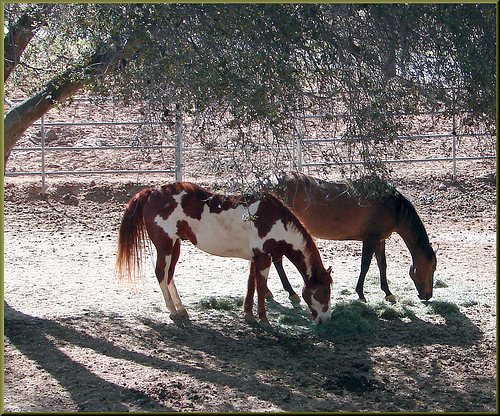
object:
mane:
[282, 195, 325, 275]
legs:
[254, 254, 274, 328]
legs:
[151, 256, 178, 320]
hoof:
[256, 311, 276, 331]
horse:
[113, 177, 337, 327]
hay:
[310, 323, 339, 339]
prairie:
[0, 176, 499, 413]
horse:
[102, 174, 458, 327]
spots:
[176, 190, 215, 221]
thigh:
[135, 188, 188, 326]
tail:
[116, 178, 152, 281]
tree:
[2, 9, 497, 172]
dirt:
[419, 179, 474, 207]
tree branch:
[51, 2, 176, 167]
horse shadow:
[166, 320, 375, 397]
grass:
[296, 326, 491, 376]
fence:
[4, 84, 498, 188]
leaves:
[17, 5, 487, 166]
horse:
[113, 166, 459, 334]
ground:
[2, 174, 492, 352]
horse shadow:
[330, 287, 479, 357]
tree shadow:
[4, 296, 402, 414]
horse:
[253, 169, 438, 319]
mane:
[393, 191, 446, 264]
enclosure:
[49, 106, 189, 178]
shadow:
[34, 338, 481, 410]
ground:
[195, 336, 320, 394]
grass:
[112, 328, 426, 366]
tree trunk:
[0, 78, 61, 170]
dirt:
[89, 153, 144, 170]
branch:
[358, 44, 435, 100]